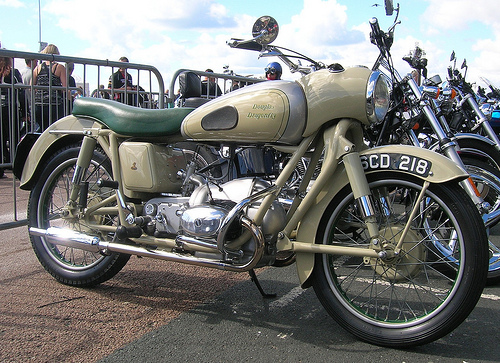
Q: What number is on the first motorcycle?
A: 218.